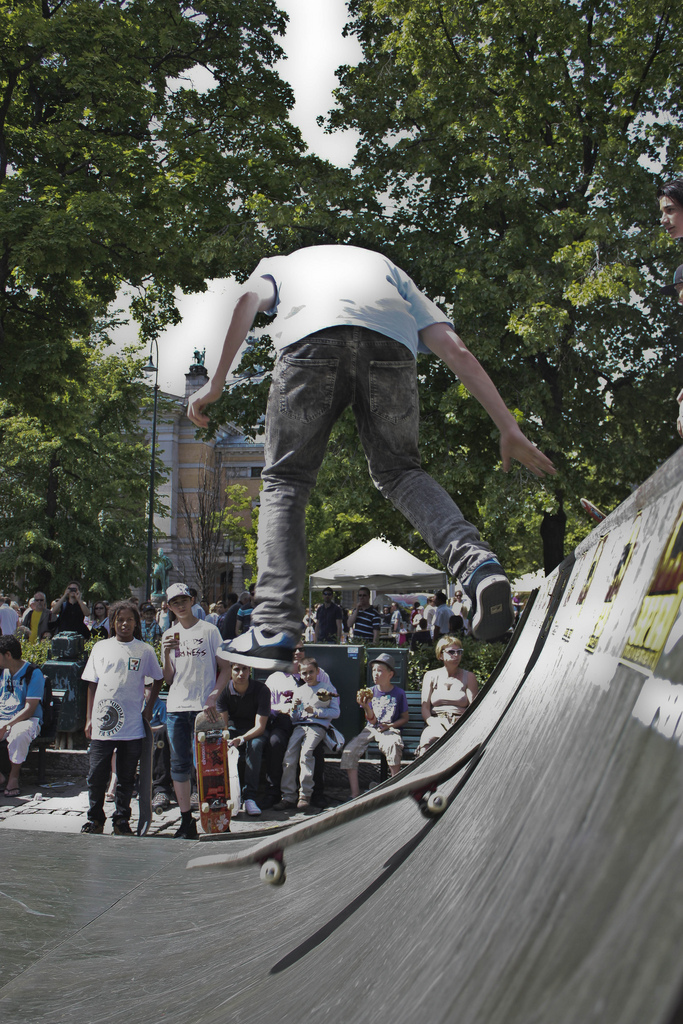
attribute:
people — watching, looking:
[89, 586, 221, 781]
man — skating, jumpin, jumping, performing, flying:
[234, 227, 504, 593]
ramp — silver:
[566, 549, 660, 925]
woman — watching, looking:
[418, 633, 497, 719]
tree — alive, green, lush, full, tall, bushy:
[382, 37, 634, 219]